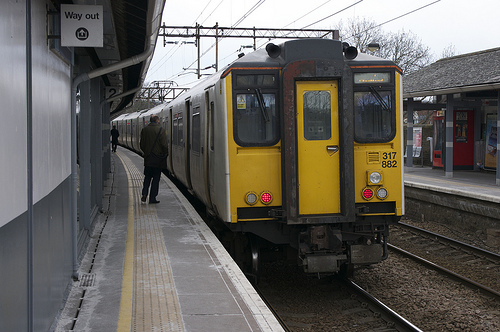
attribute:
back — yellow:
[224, 43, 401, 226]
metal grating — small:
[80, 269, 95, 289]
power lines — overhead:
[170, 1, 455, 98]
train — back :
[221, 36, 411, 266]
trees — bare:
[323, 18, 453, 75]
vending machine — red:
[429, 102, 473, 172]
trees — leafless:
[331, 15, 454, 80]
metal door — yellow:
[297, 78, 339, 217]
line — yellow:
[112, 150, 134, 330]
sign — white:
[57, 3, 104, 47]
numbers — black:
[380, 147, 400, 170]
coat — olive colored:
[140, 124, 170, 159]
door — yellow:
[297, 73, 343, 210]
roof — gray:
[393, 52, 495, 101]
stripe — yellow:
[114, 150, 134, 330]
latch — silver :
[321, 143, 340, 155]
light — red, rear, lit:
[362, 187, 374, 198]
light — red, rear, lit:
[259, 190, 271, 202]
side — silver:
[111, 70, 229, 222]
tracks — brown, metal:
[397, 209, 498, 302]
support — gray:
[443, 96, 458, 177]